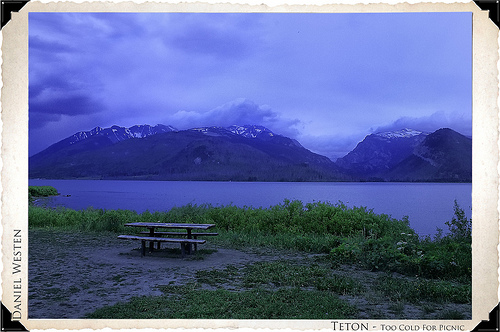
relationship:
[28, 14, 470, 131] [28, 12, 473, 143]
cloud floating in sky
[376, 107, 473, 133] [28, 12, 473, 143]
cloud floating in sky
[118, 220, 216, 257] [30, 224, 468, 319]
bench sitting on ground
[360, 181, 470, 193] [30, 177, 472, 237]
ripple in water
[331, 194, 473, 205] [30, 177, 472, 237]
ripple in water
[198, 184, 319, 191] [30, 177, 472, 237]
ripple in water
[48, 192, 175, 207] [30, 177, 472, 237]
ripple in water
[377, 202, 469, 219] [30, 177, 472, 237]
ripple in water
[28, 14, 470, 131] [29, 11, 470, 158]
cloud in sky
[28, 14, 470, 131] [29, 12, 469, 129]
cloud in sky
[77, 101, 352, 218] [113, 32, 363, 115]
fluffy in sky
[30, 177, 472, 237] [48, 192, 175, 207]
water has ripple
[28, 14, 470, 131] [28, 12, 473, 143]
cloud in sky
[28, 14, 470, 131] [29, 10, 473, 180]
cloud in sky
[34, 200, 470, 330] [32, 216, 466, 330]
grass lines up shore